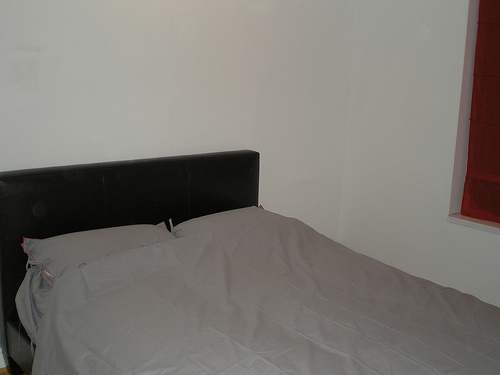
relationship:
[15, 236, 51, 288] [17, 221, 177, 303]
stitching on pillow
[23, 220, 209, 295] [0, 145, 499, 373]
pillows on bed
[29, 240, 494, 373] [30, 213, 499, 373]
fabric on cover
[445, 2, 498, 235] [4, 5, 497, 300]
window in wall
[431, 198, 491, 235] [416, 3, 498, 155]
ledge of window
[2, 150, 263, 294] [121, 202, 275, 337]
headboard of bed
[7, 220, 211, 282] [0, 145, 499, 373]
pillows on bed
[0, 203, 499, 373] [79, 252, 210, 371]
blanket on bed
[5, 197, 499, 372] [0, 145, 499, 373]
comforter on bed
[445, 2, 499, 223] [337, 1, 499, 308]
window on wall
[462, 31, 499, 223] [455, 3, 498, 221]
curtain on window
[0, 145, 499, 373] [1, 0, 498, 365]
bed in room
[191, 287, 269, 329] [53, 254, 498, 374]
creases in bedsheet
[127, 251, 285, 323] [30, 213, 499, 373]
frabric on cover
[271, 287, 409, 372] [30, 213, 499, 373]
frabric on cover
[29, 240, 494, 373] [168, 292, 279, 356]
fabric on cover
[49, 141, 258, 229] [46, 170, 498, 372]
headboard on bed